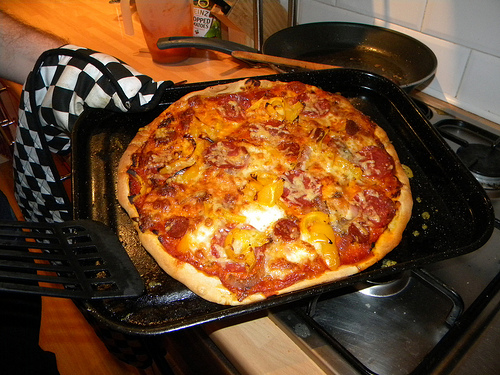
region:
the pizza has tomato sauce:
[78, 48, 465, 334]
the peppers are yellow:
[63, 16, 396, 315]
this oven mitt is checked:
[36, 34, 303, 235]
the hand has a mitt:
[14, 31, 169, 343]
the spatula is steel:
[9, 190, 126, 310]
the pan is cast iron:
[149, 20, 469, 131]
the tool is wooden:
[211, 14, 446, 129]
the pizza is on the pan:
[93, 59, 468, 341]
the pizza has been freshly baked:
[88, 27, 445, 324]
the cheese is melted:
[37, 33, 454, 322]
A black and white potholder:
[12, 42, 174, 281]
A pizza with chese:
[115, 76, 415, 310]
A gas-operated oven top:
[270, 98, 498, 372]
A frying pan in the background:
[156, 20, 438, 94]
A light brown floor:
[1, 160, 140, 374]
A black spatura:
[1, 216, 146, 301]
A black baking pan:
[73, 68, 494, 347]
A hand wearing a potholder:
[0, 9, 70, 87]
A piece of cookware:
[231, 47, 344, 72]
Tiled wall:
[282, 0, 499, 125]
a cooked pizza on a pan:
[82, 65, 447, 370]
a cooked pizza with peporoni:
[75, 77, 461, 283]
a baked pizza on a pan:
[69, 41, 447, 366]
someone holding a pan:
[46, 33, 463, 366]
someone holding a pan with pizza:
[83, 51, 399, 302]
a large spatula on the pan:
[23, 47, 499, 354]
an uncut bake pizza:
[39, 43, 466, 362]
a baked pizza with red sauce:
[100, 59, 445, 370]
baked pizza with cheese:
[92, 70, 414, 361]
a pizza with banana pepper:
[115, 47, 462, 359]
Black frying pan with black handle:
[156, 16, 440, 88]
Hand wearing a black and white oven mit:
[0, 8, 176, 274]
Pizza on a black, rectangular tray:
[57, 67, 494, 344]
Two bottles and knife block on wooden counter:
[6, 1, 301, 81]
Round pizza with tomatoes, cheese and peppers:
[114, 75, 414, 305]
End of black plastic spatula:
[7, 210, 144, 312]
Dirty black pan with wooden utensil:
[152, 12, 439, 92]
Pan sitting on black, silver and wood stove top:
[140, 18, 498, 370]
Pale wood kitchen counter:
[6, 4, 304, 97]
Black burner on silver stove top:
[420, 107, 498, 231]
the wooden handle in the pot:
[232, 48, 334, 75]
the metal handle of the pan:
[150, 35, 261, 64]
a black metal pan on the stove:
[161, 16, 432, 93]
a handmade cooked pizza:
[122, 80, 405, 295]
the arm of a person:
[2, 13, 67, 83]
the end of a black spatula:
[5, 213, 145, 302]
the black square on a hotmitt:
[35, 146, 47, 163]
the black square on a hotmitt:
[20, 127, 34, 145]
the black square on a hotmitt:
[31, 160, 45, 177]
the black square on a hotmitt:
[25, 173, 39, 190]